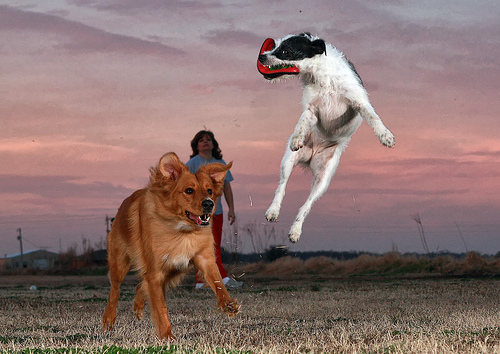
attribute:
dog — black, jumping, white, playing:
[262, 28, 397, 248]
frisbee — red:
[253, 33, 302, 79]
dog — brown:
[102, 153, 243, 337]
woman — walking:
[190, 128, 239, 290]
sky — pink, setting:
[1, 4, 497, 259]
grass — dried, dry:
[1, 257, 497, 354]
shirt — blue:
[187, 153, 233, 215]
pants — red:
[198, 211, 227, 280]